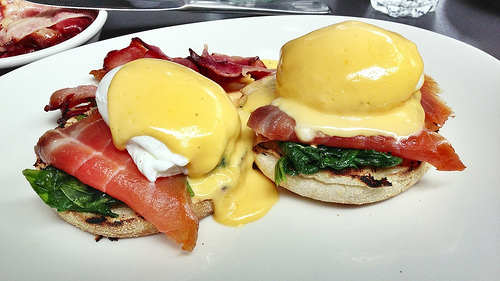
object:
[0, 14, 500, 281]
plate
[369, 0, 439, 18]
glass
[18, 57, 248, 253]
sandwich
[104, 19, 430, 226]
sauce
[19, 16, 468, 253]
food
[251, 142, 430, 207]
muffin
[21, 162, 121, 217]
spinach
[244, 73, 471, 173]
fish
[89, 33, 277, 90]
bacon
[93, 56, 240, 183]
egg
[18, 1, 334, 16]
knife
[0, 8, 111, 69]
dish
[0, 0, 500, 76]
table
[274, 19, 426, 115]
eggs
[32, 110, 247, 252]
ham